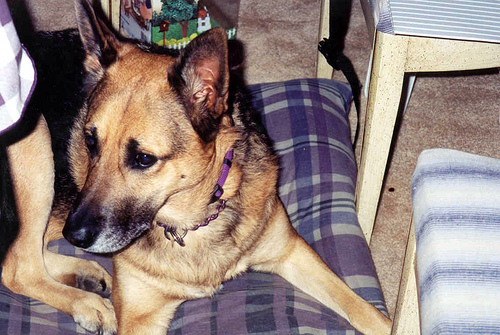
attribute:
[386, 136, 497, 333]
chair — striped, blue, white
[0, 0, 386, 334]
dog — sad looking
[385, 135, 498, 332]
pillow — patterned, purple and grey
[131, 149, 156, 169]
eye — big